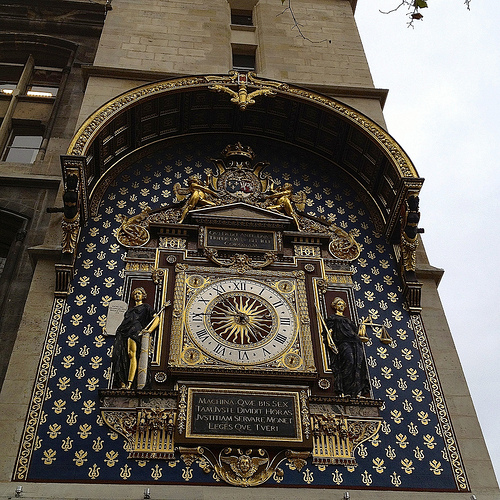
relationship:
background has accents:
[377, 352, 427, 454] [31, 125, 428, 460]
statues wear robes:
[104, 274, 362, 404] [112, 302, 368, 392]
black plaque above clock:
[201, 226, 279, 254] [183, 267, 314, 370]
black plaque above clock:
[191, 387, 301, 442] [183, 267, 314, 370]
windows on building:
[209, 7, 279, 80] [48, 5, 385, 435]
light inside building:
[0, 77, 55, 102] [0, 1, 498, 496]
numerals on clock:
[193, 282, 290, 359] [183, 267, 314, 370]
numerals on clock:
[236, 347, 248, 360] [183, 267, 314, 370]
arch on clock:
[57, 67, 424, 242] [183, 275, 297, 365]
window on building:
[0, 33, 80, 160] [0, 1, 498, 496]